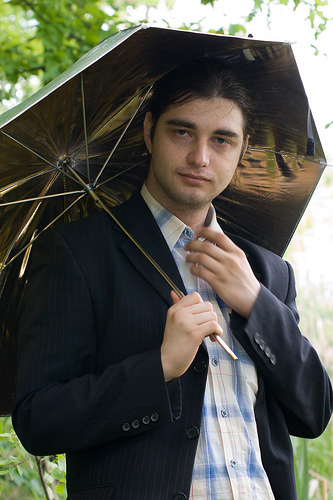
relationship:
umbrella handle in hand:
[81, 181, 246, 363] [156, 266, 223, 385]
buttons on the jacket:
[123, 412, 159, 434] [44, 191, 327, 490]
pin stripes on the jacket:
[124, 448, 174, 487] [25, 200, 207, 495]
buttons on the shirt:
[184, 226, 238, 469] [141, 182, 279, 498]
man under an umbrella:
[12, 55, 331, 495] [0, 23, 331, 416]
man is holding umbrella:
[12, 55, 331, 495] [0, 23, 331, 416]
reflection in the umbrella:
[270, 108, 323, 202] [8, 79, 319, 263]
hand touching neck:
[185, 226, 256, 309] [144, 175, 210, 239]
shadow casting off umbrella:
[154, 87, 320, 197] [0, 23, 331, 416]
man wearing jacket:
[12, 55, 331, 495] [10, 189, 332, 500]